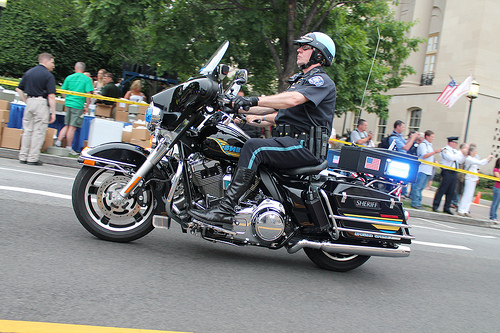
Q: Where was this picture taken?
A: The street.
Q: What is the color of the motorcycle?
A: Black.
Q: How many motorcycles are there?
A: One.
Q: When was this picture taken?
A: Daytime.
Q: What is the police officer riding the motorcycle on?
A: The street.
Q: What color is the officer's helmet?
A: Aqua.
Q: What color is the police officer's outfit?
A: Blue.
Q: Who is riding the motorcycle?
A: A police officer.